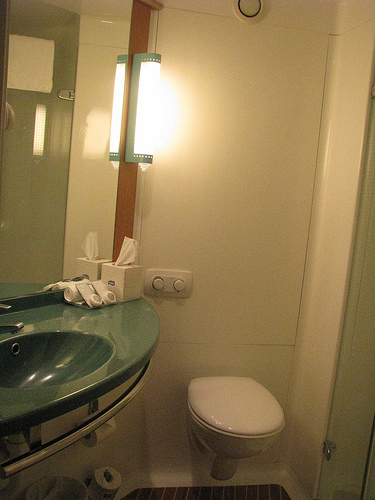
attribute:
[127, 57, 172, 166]
light — on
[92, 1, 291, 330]
wall — white, tan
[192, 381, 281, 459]
toilet — white, shiny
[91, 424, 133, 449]
toilet paper — under, unpackaged, new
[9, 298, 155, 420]
sink — green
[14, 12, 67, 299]
door — green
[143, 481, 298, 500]
floor — tiled, brown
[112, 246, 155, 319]
tissues — white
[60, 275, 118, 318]
towel — rolled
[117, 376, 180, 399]
rail — shiny, metal